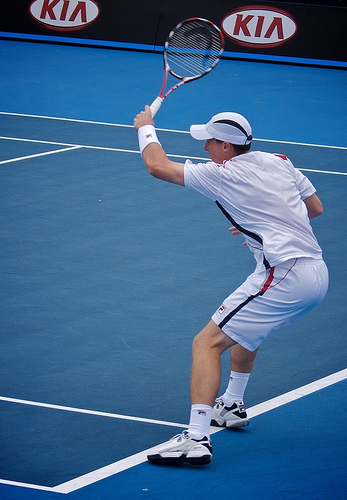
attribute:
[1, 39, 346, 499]
court — blue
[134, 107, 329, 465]
man — waiting, playing tennis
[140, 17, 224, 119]
racket — black, white, red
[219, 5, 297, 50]
advertisement — for auto maker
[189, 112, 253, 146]
cap — black, white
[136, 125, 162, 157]
wristband — white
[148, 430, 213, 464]
shoe — white, partly black, black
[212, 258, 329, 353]
shorts — white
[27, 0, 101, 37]
logo — kia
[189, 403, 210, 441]
sock — white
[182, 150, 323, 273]
shirt — white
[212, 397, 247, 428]
shoe — partly black